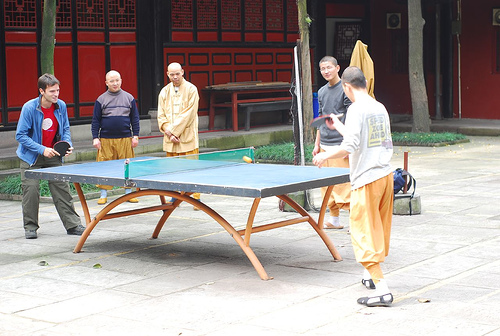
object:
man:
[310, 55, 370, 235]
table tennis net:
[125, 145, 256, 180]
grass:
[0, 130, 470, 201]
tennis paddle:
[53, 140, 71, 157]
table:
[201, 84, 295, 132]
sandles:
[97, 194, 139, 204]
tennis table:
[23, 146, 352, 280]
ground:
[1, 131, 498, 311]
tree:
[0, 0, 432, 193]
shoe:
[97, 196, 201, 212]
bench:
[225, 100, 295, 132]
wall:
[0, 0, 499, 131]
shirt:
[318, 79, 354, 146]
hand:
[169, 134, 180, 143]